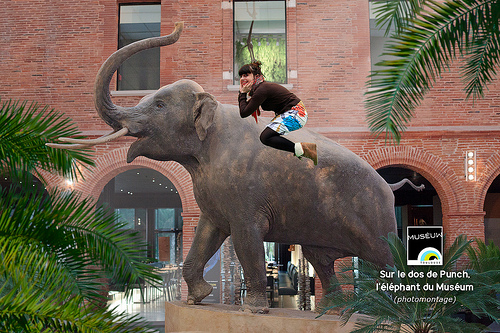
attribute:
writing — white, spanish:
[375, 268, 475, 302]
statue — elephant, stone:
[43, 23, 431, 316]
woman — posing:
[237, 65, 320, 163]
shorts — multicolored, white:
[272, 100, 308, 131]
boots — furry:
[302, 141, 322, 166]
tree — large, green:
[3, 99, 162, 332]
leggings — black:
[261, 127, 296, 153]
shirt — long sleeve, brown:
[236, 86, 302, 112]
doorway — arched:
[88, 162, 179, 277]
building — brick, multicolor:
[3, 0, 499, 319]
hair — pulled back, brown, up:
[235, 59, 264, 80]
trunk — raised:
[92, 22, 180, 123]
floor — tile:
[109, 284, 170, 319]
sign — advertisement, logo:
[406, 225, 444, 268]